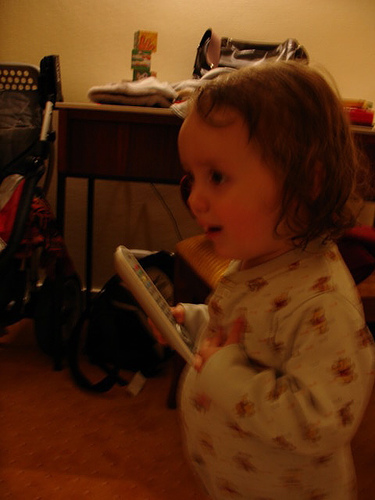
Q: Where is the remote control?
A: Child's hand.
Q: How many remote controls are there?
A: One.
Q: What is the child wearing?
A: Pajamas.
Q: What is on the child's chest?
A: Hand.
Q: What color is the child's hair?
A: Brown.